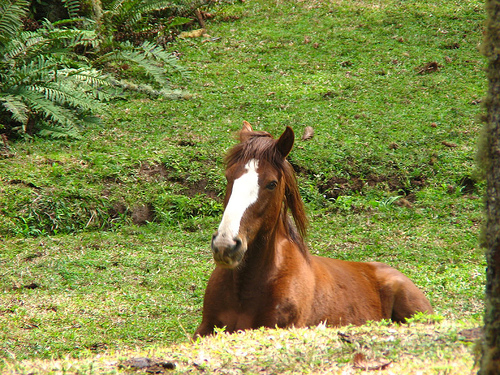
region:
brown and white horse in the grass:
[200, 108, 428, 348]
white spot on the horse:
[219, 160, 256, 254]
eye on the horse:
[263, 177, 285, 194]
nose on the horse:
[210, 229, 250, 286]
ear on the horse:
[275, 123, 306, 175]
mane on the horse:
[286, 160, 311, 237]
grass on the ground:
[50, 252, 140, 332]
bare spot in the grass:
[127, 188, 150, 225]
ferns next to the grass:
[9, 35, 81, 115]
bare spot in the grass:
[338, 154, 407, 207]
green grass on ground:
[0, 3, 485, 360]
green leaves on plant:
[6, 4, 195, 132]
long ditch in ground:
[25, 151, 452, 242]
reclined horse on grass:
[201, 121, 430, 338]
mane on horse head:
[226, 130, 276, 168]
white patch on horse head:
[215, 162, 262, 255]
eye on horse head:
[262, 176, 279, 192]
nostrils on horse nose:
[207, 233, 244, 252]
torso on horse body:
[300, 260, 380, 325]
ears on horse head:
[239, 115, 294, 157]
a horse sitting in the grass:
[169, 138, 461, 339]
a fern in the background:
[0, 36, 110, 138]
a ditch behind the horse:
[3, 161, 499, 226]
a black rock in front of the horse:
[115, 353, 175, 374]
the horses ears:
[232, 105, 309, 157]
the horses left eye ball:
[257, 174, 283, 196]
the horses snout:
[192, 156, 270, 278]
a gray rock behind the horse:
[297, 116, 335, 143]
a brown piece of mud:
[109, 188, 159, 230]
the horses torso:
[189, 242, 429, 341]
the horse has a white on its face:
[215, 154, 261, 243]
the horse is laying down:
[184, 111, 449, 348]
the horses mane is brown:
[240, 130, 275, 165]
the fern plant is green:
[1, 3, 185, 148]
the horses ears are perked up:
[266, 125, 299, 160]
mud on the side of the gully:
[128, 203, 154, 223]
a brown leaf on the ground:
[349, 353, 389, 374]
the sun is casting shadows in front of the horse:
[193, 326, 472, 373]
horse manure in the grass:
[124, 359, 182, 371]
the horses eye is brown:
[265, 178, 280, 191]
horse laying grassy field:
[186, 123, 473, 319]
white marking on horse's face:
[212, 150, 257, 242]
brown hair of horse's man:
[224, 132, 311, 231]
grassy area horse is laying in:
[15, 6, 475, 373]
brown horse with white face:
[204, 120, 419, 324]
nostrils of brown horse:
[207, 238, 248, 260]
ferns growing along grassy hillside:
[2, 5, 170, 117]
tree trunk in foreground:
[471, 0, 498, 374]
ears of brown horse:
[235, 120, 295, 153]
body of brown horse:
[215, 254, 416, 320]